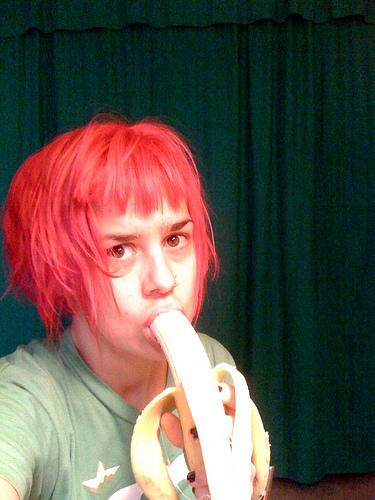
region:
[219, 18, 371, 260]
large green drapes in background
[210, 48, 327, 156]
pleats in green drapes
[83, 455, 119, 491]
white logo on tee shirt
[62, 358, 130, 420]
collar on green shirt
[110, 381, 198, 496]
yellow banana peel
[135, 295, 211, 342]
banana in woman's mouth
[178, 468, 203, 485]
dark nail polish on woman's hand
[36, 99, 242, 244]
orange hair on woman's head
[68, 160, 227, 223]
jagged bangs on woman's head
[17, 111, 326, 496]
woman eating yellow banana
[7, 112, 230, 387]
Woman has brown eyes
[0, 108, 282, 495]
Woman wears a wig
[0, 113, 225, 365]
Wig of woman is red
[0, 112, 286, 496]
Woman wears a green t-shirt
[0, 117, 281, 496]
Woman is eating a banana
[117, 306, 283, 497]
Banana is peel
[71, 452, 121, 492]
Yellow star on t-shirt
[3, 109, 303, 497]
Woman has a banana in her mouth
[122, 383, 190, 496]
Peel of banana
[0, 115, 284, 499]
Woman holds a banana with left hand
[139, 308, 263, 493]
Large ripe banana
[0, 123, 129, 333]
Red hair on a woman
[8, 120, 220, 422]
Young woman eating a banana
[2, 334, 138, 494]
Green shirt with white design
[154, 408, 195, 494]
Painted finger nails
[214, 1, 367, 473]
long dark green curtains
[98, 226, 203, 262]
Woman's brown eyes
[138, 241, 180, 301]
Nose of a woman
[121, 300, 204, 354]
Woman's lips around a banana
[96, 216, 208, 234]
Eyebrows of woman with brown eyes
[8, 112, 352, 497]
a boy eating a banana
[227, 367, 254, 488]
a yellow peel hanging off the banana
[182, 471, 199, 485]
dark nail polish on a finger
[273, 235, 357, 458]
a large blue curtain behind the person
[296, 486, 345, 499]
wood covering the floor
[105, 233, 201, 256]
brown eyes in a face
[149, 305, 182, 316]
pink lips around a banana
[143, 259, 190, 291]
a nose in a face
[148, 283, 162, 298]
a nostril in the nose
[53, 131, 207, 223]
bright red hair on a head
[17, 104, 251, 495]
Woman with red hair.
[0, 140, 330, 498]
Woman eating a banana.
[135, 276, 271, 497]
Banana in the woman's mouth.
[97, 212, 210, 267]
The woman's eyes are brown.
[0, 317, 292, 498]
Green shirt on the woman.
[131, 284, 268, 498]
The banana is yellow.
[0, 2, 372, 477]
Large curtain behind the woman.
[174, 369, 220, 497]
The woman's fingernails are painted.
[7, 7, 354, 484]
Curtain behind the woman is green.